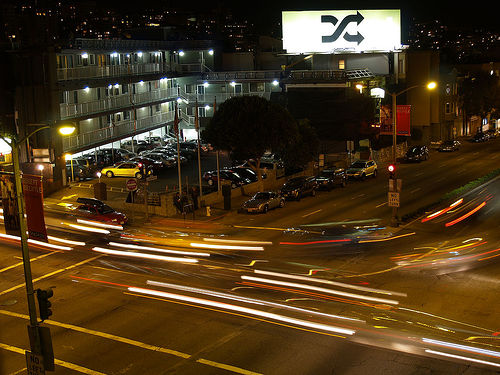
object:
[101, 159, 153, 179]
car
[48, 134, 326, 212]
lot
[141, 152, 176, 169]
car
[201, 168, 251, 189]
car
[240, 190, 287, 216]
car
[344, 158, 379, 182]
car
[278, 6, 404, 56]
sign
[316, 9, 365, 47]
arrow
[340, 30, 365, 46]
arrow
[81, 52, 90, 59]
outside lighting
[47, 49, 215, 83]
floor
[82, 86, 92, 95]
outside lighting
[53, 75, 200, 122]
floor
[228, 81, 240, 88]
outside lighting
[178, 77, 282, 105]
floor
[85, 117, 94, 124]
outside lighting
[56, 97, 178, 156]
floor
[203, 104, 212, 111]
outside lighting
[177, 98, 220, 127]
floor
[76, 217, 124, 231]
light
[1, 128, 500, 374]
street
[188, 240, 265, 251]
light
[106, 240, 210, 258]
light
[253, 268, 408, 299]
light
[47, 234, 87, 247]
light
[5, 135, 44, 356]
lamppost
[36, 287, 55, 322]
traffic light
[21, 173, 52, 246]
banner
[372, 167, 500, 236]
island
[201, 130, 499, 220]
curb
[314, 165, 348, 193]
car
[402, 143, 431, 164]
car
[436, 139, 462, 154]
car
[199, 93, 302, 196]
tree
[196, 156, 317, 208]
wall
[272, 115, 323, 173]
tree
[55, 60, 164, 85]
railing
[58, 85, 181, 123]
railing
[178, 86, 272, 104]
railing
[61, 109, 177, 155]
railing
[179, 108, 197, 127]
railing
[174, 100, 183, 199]
pole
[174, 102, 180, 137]
flag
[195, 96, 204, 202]
pole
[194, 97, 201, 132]
flag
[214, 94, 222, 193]
pole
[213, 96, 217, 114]
flag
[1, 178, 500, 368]
traffic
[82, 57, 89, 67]
balcony door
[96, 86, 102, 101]
balcony door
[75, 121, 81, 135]
balcony door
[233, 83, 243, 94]
balcony door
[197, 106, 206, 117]
balcony door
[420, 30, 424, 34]
city light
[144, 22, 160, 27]
city light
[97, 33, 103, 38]
city light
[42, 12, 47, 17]
city light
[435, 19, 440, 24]
city light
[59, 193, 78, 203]
arrow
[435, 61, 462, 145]
storefront building